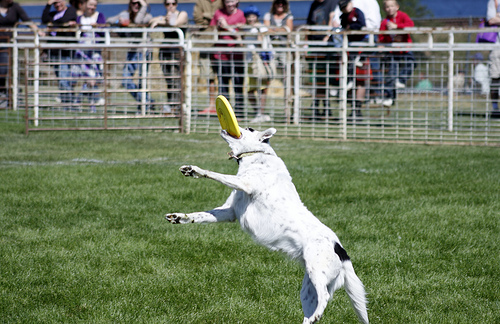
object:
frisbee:
[213, 92, 241, 138]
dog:
[165, 126, 371, 323]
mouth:
[220, 128, 249, 143]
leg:
[179, 164, 258, 195]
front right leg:
[165, 202, 248, 223]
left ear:
[256, 127, 278, 141]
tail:
[331, 239, 369, 324]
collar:
[228, 152, 280, 159]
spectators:
[42, 0, 82, 107]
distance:
[1, 0, 499, 148]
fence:
[347, 28, 498, 142]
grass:
[3, 143, 498, 321]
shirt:
[209, 11, 245, 60]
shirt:
[376, 10, 413, 54]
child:
[379, 0, 412, 109]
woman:
[153, 1, 190, 120]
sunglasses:
[165, 1, 178, 9]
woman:
[211, 0, 248, 125]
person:
[42, 1, 78, 107]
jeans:
[50, 52, 76, 107]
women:
[107, 0, 148, 117]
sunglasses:
[130, 1, 139, 7]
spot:
[332, 243, 351, 261]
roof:
[416, 17, 487, 26]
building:
[416, 16, 488, 95]